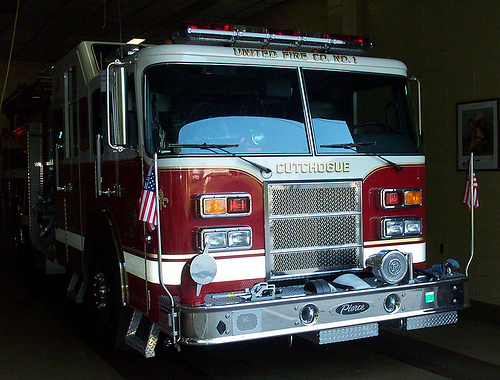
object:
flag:
[138, 162, 162, 231]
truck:
[0, 26, 471, 359]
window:
[145, 63, 421, 157]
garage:
[0, 1, 499, 379]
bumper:
[180, 274, 468, 345]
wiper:
[169, 143, 271, 173]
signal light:
[204, 196, 225, 214]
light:
[227, 196, 250, 213]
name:
[233, 48, 357, 65]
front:
[139, 45, 469, 340]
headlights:
[200, 191, 421, 250]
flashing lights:
[188, 22, 362, 44]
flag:
[461, 151, 479, 211]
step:
[124, 313, 160, 357]